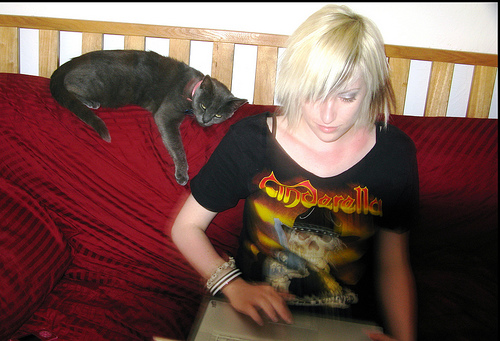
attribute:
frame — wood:
[0, 16, 496, 116]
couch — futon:
[0, 66, 498, 339]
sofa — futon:
[4, 13, 499, 337]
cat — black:
[49, 50, 246, 145]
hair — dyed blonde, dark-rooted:
[277, 0, 399, 135]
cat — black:
[48, 47, 247, 186]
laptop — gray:
[218, 292, 336, 335]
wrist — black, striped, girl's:
[190, 237, 282, 317]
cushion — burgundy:
[0, 70, 494, 339]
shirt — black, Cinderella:
[183, 123, 420, 320]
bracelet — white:
[208, 270, 240, 294]